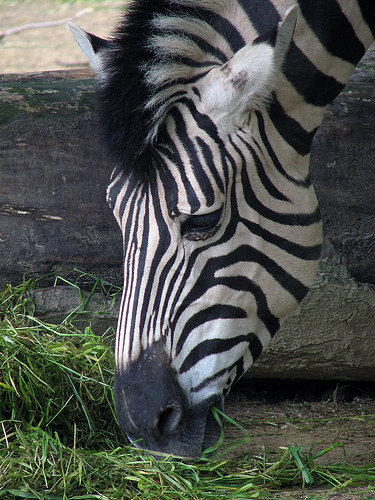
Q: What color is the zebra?
A: Black and white.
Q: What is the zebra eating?
A: Grass.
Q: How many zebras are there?
A: One.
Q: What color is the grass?
A: Green.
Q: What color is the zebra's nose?
A: Black.